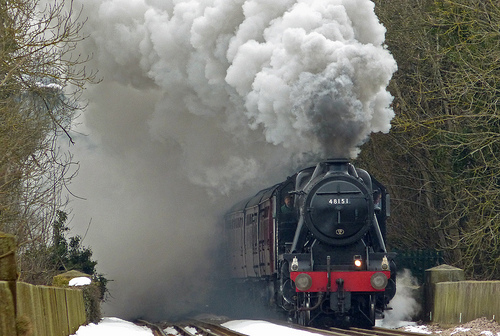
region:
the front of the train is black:
[287, 157, 406, 292]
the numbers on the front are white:
[322, 191, 362, 213]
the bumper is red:
[278, 259, 410, 299]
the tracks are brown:
[137, 316, 239, 334]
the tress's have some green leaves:
[431, 132, 488, 206]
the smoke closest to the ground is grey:
[117, 210, 215, 290]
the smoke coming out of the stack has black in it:
[296, 75, 391, 170]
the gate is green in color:
[394, 241, 449, 281]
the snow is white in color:
[222, 315, 292, 335]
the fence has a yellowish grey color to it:
[431, 274, 494, 322]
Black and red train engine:
[236, 156, 416, 318]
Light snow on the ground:
[207, 300, 319, 333]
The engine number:
[321, 187, 363, 208]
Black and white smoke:
[271, 33, 416, 163]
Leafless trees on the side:
[406, 71, 498, 229]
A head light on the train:
[340, 254, 397, 269]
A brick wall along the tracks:
[13, 256, 98, 333]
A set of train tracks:
[134, 304, 244, 334]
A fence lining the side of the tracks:
[390, 230, 462, 308]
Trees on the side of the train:
[3, 4, 134, 308]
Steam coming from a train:
[296, 52, 389, 228]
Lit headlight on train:
[335, 247, 365, 274]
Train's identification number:
[321, 189, 358, 210]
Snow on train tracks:
[86, 309, 291, 334]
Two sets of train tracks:
[142, 315, 430, 334]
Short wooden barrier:
[1, 269, 106, 334]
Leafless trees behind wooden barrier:
[427, 5, 497, 326]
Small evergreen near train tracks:
[44, 209, 220, 334]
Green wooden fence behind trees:
[393, 232, 493, 269]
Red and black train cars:
[226, 178, 291, 287]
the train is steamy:
[69, 13, 387, 283]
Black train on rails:
[195, 164, 422, 333]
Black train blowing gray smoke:
[161, 15, 399, 326]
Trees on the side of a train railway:
[333, 1, 497, 333]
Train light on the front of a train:
[319, 238, 383, 323]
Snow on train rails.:
[76, 297, 481, 332]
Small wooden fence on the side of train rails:
[3, 246, 243, 333]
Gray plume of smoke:
[83, 7, 365, 155]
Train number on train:
[308, 145, 373, 208]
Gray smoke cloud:
[94, 168, 240, 330]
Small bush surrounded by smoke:
[49, 152, 227, 271]